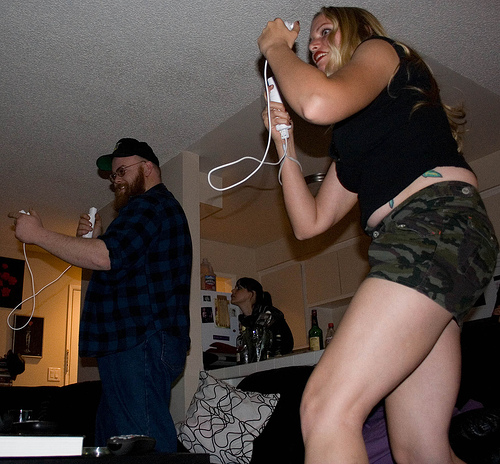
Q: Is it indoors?
A: Yes, it is indoors.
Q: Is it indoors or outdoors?
A: It is indoors.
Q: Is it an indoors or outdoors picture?
A: It is indoors.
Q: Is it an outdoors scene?
A: No, it is indoors.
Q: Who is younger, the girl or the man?
A: The girl is younger than the man.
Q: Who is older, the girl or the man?
A: The man is older than the girl.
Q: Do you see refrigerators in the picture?
A: Yes, there is a refrigerator.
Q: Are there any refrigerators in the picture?
A: Yes, there is a refrigerator.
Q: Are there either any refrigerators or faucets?
A: Yes, there is a refrigerator.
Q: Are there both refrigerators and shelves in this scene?
A: No, there is a refrigerator but no shelves.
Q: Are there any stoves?
A: No, there are no stoves.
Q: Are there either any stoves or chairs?
A: No, there are no stoves or chairs.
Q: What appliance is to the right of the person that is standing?
A: The appliance is a refrigerator.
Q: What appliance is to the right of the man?
A: The appliance is a refrigerator.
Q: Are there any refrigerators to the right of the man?
A: Yes, there is a refrigerator to the right of the man.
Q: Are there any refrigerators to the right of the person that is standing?
A: Yes, there is a refrigerator to the right of the man.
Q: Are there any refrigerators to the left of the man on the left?
A: No, the refrigerator is to the right of the man.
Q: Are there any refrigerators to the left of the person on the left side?
A: No, the refrigerator is to the right of the man.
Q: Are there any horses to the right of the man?
A: No, there is a refrigerator to the right of the man.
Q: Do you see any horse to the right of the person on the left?
A: No, there is a refrigerator to the right of the man.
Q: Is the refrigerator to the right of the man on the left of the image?
A: Yes, the refrigerator is to the right of the man.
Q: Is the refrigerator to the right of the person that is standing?
A: Yes, the refrigerator is to the right of the man.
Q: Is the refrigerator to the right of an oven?
A: No, the refrigerator is to the right of the man.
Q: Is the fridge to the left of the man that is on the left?
A: No, the fridge is to the right of the man.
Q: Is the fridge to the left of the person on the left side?
A: No, the fridge is to the right of the man.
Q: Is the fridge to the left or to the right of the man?
A: The fridge is to the right of the man.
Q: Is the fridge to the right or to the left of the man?
A: The fridge is to the right of the man.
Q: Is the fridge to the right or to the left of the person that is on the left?
A: The fridge is to the right of the man.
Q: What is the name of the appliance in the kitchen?
A: The appliance is a refrigerator.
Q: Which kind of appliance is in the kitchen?
A: The appliance is a refrigerator.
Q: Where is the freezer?
A: The freezer is in the kitchen.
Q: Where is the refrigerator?
A: The freezer is in the kitchen.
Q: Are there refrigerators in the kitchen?
A: Yes, there is a refrigerator in the kitchen.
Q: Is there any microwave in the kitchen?
A: No, there is a refrigerator in the kitchen.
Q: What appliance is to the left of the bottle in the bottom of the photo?
A: The appliance is a refrigerator.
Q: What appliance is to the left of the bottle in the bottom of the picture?
A: The appliance is a refrigerator.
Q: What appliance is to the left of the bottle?
A: The appliance is a refrigerator.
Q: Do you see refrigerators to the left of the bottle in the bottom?
A: Yes, there is a refrigerator to the left of the bottle.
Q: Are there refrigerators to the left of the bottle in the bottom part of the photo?
A: Yes, there is a refrigerator to the left of the bottle.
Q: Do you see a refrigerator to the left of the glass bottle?
A: Yes, there is a refrigerator to the left of the bottle.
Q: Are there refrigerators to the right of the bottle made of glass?
A: No, the refrigerator is to the left of the bottle.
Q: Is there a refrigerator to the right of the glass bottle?
A: No, the refrigerator is to the left of the bottle.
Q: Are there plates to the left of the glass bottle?
A: No, there is a refrigerator to the left of the bottle.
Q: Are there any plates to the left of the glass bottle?
A: No, there is a refrigerator to the left of the bottle.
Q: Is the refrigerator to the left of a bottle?
A: Yes, the refrigerator is to the left of a bottle.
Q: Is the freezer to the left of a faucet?
A: No, the freezer is to the left of a bottle.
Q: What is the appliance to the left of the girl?
A: The appliance is a refrigerator.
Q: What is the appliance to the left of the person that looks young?
A: The appliance is a refrigerator.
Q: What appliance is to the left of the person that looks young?
A: The appliance is a refrigerator.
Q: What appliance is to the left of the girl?
A: The appliance is a refrigerator.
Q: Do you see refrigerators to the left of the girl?
A: Yes, there is a refrigerator to the left of the girl.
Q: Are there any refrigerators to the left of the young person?
A: Yes, there is a refrigerator to the left of the girl.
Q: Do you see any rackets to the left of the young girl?
A: No, there is a refrigerator to the left of the girl.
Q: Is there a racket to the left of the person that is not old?
A: No, there is a refrigerator to the left of the girl.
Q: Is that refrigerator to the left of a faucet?
A: No, the refrigerator is to the left of a girl.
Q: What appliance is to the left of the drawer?
A: The appliance is a refrigerator.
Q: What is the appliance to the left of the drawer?
A: The appliance is a refrigerator.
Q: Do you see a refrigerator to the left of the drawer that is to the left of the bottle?
A: Yes, there is a refrigerator to the left of the drawer.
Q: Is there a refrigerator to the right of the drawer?
A: No, the refrigerator is to the left of the drawer.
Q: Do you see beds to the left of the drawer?
A: No, there is a refrigerator to the left of the drawer.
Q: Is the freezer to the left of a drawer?
A: Yes, the freezer is to the left of a drawer.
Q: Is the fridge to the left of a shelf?
A: No, the fridge is to the left of a drawer.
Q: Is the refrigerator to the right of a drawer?
A: No, the refrigerator is to the left of a drawer.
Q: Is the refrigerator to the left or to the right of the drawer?
A: The refrigerator is to the left of the drawer.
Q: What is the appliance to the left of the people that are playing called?
A: The appliance is a refrigerator.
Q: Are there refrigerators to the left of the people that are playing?
A: Yes, there is a refrigerator to the left of the people.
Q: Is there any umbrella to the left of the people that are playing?
A: No, there is a refrigerator to the left of the people.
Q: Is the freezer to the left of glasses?
A: No, the freezer is to the left of the people.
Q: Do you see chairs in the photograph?
A: No, there are no chairs.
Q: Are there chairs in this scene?
A: No, there are no chairs.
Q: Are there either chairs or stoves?
A: No, there are no chairs or stoves.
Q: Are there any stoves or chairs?
A: No, there are no chairs or stoves.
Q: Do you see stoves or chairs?
A: No, there are no chairs or stoves.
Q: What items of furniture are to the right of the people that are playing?
A: The pieces of furniture are cabinets.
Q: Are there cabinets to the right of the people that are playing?
A: Yes, there are cabinets to the right of the people.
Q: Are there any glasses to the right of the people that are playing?
A: No, there are cabinets to the right of the people.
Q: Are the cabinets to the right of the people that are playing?
A: Yes, the cabinets are to the right of the people.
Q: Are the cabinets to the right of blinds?
A: No, the cabinets are to the right of the people.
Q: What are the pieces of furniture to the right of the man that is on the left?
A: The pieces of furniture are cabinets.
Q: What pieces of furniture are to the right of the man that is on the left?
A: The pieces of furniture are cabinets.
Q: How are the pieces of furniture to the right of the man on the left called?
A: The pieces of furniture are cabinets.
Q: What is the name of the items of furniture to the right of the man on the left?
A: The pieces of furniture are cabinets.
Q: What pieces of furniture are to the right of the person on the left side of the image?
A: The pieces of furniture are cabinets.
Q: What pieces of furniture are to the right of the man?
A: The pieces of furniture are cabinets.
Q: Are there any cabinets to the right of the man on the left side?
A: Yes, there are cabinets to the right of the man.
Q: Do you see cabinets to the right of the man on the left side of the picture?
A: Yes, there are cabinets to the right of the man.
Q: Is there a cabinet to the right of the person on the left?
A: Yes, there are cabinets to the right of the man.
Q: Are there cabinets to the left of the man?
A: No, the cabinets are to the right of the man.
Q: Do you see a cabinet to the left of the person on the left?
A: No, the cabinets are to the right of the man.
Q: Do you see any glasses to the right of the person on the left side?
A: No, there are cabinets to the right of the man.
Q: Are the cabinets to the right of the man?
A: Yes, the cabinets are to the right of the man.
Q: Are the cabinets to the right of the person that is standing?
A: Yes, the cabinets are to the right of the man.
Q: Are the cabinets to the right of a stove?
A: No, the cabinets are to the right of the man.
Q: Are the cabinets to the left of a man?
A: No, the cabinets are to the right of a man.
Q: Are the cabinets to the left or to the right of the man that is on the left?
A: The cabinets are to the right of the man.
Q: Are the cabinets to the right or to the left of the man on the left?
A: The cabinets are to the right of the man.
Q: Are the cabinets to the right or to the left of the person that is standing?
A: The cabinets are to the right of the man.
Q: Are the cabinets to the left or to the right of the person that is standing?
A: The cabinets are to the right of the man.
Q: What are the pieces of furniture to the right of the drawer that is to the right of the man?
A: The pieces of furniture are cabinets.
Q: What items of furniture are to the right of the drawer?
A: The pieces of furniture are cabinets.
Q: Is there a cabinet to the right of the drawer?
A: Yes, there are cabinets to the right of the drawer.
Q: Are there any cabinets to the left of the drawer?
A: No, the cabinets are to the right of the drawer.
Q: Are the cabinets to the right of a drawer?
A: Yes, the cabinets are to the right of a drawer.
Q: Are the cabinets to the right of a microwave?
A: No, the cabinets are to the right of a drawer.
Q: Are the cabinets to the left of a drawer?
A: No, the cabinets are to the right of a drawer.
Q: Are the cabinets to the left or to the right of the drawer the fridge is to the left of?
A: The cabinets are to the right of the drawer.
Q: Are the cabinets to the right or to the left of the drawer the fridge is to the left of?
A: The cabinets are to the right of the drawer.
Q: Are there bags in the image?
A: No, there are no bags.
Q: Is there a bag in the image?
A: No, there are no bags.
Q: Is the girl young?
A: Yes, the girl is young.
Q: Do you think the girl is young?
A: Yes, the girl is young.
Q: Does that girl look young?
A: Yes, the girl is young.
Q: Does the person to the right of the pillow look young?
A: Yes, the girl is young.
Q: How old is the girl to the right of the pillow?
A: The girl is young.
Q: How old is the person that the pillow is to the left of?
A: The girl is young.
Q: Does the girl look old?
A: No, the girl is young.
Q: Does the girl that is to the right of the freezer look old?
A: No, the girl is young.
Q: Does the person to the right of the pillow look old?
A: No, the girl is young.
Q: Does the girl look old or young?
A: The girl is young.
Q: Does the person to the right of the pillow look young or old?
A: The girl is young.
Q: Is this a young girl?
A: Yes, this is a young girl.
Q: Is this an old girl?
A: No, this is a young girl.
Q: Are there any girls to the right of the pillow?
A: Yes, there is a girl to the right of the pillow.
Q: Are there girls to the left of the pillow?
A: No, the girl is to the right of the pillow.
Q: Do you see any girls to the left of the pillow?
A: No, the girl is to the right of the pillow.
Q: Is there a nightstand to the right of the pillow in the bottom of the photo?
A: No, there is a girl to the right of the pillow.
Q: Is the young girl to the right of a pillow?
A: Yes, the girl is to the right of a pillow.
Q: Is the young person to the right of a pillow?
A: Yes, the girl is to the right of a pillow.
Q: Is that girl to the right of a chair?
A: No, the girl is to the right of a pillow.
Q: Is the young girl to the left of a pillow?
A: No, the girl is to the right of a pillow.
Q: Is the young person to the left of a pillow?
A: No, the girl is to the right of a pillow.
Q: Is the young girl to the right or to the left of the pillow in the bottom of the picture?
A: The girl is to the right of the pillow.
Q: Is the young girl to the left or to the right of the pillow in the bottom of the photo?
A: The girl is to the right of the pillow.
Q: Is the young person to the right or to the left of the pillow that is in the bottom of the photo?
A: The girl is to the right of the pillow.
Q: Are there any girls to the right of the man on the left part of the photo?
A: Yes, there is a girl to the right of the man.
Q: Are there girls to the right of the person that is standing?
A: Yes, there is a girl to the right of the man.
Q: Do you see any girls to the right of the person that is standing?
A: Yes, there is a girl to the right of the man.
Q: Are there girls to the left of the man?
A: No, the girl is to the right of the man.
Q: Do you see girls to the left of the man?
A: No, the girl is to the right of the man.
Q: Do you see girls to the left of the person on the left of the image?
A: No, the girl is to the right of the man.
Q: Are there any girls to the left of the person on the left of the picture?
A: No, the girl is to the right of the man.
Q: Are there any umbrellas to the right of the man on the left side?
A: No, there is a girl to the right of the man.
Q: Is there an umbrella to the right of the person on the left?
A: No, there is a girl to the right of the man.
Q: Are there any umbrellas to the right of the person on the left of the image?
A: No, there is a girl to the right of the man.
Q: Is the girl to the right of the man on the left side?
A: Yes, the girl is to the right of the man.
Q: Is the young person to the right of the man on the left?
A: Yes, the girl is to the right of the man.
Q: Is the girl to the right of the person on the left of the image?
A: Yes, the girl is to the right of the man.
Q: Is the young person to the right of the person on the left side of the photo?
A: Yes, the girl is to the right of the man.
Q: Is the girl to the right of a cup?
A: No, the girl is to the right of the man.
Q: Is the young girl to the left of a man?
A: No, the girl is to the right of a man.